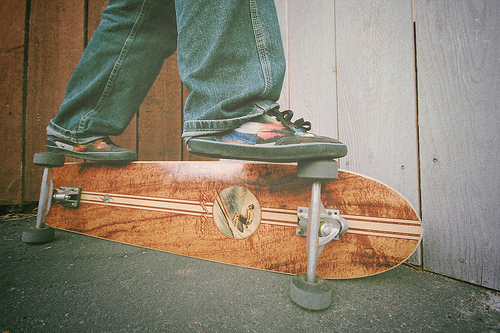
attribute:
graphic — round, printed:
[211, 186, 264, 237]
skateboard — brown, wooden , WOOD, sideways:
[27, 151, 425, 311]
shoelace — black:
[273, 104, 313, 142]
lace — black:
[279, 110, 325, 143]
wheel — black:
[287, 269, 335, 314]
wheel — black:
[19, 212, 51, 239]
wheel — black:
[29, 144, 71, 174]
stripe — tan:
[79, 189, 422, 244]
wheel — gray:
[32, 151, 66, 167]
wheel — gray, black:
[293, 157, 340, 180]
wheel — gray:
[22, 226, 56, 245]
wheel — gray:
[286, 275, 335, 311]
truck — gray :
[32, 165, 82, 230]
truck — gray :
[296, 178, 350, 285]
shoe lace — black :
[267, 108, 315, 134]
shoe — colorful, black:
[182, 107, 350, 161]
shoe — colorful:
[45, 135, 138, 162]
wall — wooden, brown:
[6, 0, 211, 209]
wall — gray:
[276, 1, 498, 290]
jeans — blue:
[52, 0, 288, 132]